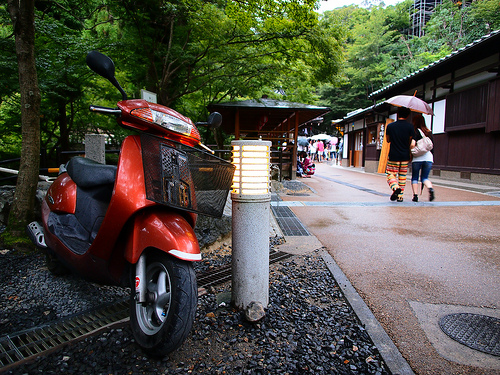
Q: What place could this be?
A: It is a walkway.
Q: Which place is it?
A: It is a walkway.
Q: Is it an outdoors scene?
A: Yes, it is outdoors.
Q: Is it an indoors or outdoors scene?
A: It is outdoors.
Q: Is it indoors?
A: No, it is outdoors.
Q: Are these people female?
A: No, they are both male and female.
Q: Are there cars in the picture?
A: No, there are no cars.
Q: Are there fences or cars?
A: No, there are no cars or fences.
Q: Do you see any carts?
A: No, there are no carts.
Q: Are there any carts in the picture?
A: No, there are no carts.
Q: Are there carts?
A: No, there are no carts.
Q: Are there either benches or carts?
A: No, there are no carts or benches.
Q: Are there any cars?
A: No, there are no cars.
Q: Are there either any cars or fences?
A: No, there are no cars or fences.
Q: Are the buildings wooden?
A: Yes, the buildings are wooden.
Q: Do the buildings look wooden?
A: Yes, the buildings are wooden.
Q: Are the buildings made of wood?
A: Yes, the buildings are made of wood.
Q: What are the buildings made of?
A: The buildings are made of wood.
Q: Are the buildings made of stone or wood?
A: The buildings are made of wood.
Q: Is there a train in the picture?
A: No, there are no trains.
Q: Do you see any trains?
A: No, there are no trains.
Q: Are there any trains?
A: No, there are no trains.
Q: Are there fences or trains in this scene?
A: No, there are no trains or fences.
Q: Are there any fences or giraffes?
A: No, there are no fences or giraffes.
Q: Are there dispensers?
A: No, there are no dispensers.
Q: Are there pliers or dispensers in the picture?
A: No, there are no dispensers or pliers.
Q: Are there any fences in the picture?
A: No, there are no fences.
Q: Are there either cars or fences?
A: No, there are no fences or cars.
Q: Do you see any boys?
A: No, there are no boys.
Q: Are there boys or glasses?
A: No, there are no boys or glasses.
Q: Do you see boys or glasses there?
A: No, there are no boys or glasses.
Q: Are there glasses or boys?
A: No, there are no boys or glasses.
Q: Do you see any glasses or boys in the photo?
A: No, there are no boys or glasses.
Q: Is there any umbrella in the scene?
A: Yes, there is an umbrella.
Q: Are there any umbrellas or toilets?
A: Yes, there is an umbrella.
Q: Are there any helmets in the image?
A: No, there are no helmets.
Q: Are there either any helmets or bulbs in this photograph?
A: No, there are no helmets or bulbs.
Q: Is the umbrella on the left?
A: No, the umbrella is on the right of the image.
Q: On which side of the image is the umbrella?
A: The umbrella is on the right of the image.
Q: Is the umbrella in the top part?
A: Yes, the umbrella is in the top of the image.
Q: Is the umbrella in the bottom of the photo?
A: No, the umbrella is in the top of the image.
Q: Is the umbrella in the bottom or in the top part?
A: The umbrella is in the top of the image.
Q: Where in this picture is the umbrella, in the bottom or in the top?
A: The umbrella is in the top of the image.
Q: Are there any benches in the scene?
A: No, there are no benches.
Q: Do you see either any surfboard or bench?
A: No, there are no benches or surfboards.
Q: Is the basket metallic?
A: Yes, the basket is metallic.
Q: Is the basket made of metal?
A: Yes, the basket is made of metal.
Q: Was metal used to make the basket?
A: Yes, the basket is made of metal.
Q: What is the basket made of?
A: The basket is made of metal.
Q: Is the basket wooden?
A: No, the basket is metallic.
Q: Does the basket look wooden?
A: No, the basket is metallic.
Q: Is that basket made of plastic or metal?
A: The basket is made of metal.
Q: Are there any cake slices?
A: No, there are no cake slices.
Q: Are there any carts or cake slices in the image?
A: No, there are no cake slices or carts.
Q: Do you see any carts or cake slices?
A: No, there are no cake slices or carts.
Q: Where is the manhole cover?
A: The manhole cover is on the street.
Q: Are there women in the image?
A: Yes, there is a woman.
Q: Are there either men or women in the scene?
A: Yes, there is a woman.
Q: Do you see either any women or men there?
A: Yes, there is a woman.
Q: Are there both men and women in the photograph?
A: Yes, there are both a woman and a man.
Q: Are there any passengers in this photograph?
A: No, there are no passengers.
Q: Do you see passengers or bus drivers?
A: No, there are no passengers or bus drivers.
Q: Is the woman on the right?
A: Yes, the woman is on the right of the image.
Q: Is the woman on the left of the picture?
A: No, the woman is on the right of the image.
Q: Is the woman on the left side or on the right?
A: The woman is on the right of the image.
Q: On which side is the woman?
A: The woman is on the right of the image.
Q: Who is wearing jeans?
A: The woman is wearing jeans.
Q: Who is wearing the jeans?
A: The woman is wearing jeans.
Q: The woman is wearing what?
A: The woman is wearing jeans.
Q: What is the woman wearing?
A: The woman is wearing jeans.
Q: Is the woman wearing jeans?
A: Yes, the woman is wearing jeans.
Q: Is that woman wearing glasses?
A: No, the woman is wearing jeans.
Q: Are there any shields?
A: No, there are no shields.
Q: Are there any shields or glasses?
A: No, there are no shields or glasses.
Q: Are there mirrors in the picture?
A: Yes, there is a mirror.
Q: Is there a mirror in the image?
A: Yes, there is a mirror.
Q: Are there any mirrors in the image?
A: Yes, there is a mirror.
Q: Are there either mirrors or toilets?
A: Yes, there is a mirror.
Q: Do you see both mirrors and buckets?
A: No, there is a mirror but no buckets.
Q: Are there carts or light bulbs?
A: No, there are no carts or light bulbs.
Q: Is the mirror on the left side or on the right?
A: The mirror is on the left of the image.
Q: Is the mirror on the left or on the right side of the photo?
A: The mirror is on the left of the image.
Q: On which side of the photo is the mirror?
A: The mirror is on the left of the image.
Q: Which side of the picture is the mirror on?
A: The mirror is on the left of the image.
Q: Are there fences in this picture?
A: No, there are no fences.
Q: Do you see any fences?
A: No, there are no fences.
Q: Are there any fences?
A: No, there are no fences.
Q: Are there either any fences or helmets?
A: No, there are no fences or helmets.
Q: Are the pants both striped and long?
A: Yes, the pants are striped and long.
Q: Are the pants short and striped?
A: No, the pants are striped but long.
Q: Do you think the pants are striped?
A: Yes, the pants are striped.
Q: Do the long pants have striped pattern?
A: Yes, the pants are striped.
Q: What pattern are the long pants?
A: The trousers are striped.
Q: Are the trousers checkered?
A: No, the trousers are striped.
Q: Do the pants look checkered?
A: No, the pants are striped.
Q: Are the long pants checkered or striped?
A: The pants are striped.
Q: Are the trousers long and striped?
A: Yes, the trousers are long and striped.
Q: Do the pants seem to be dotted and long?
A: No, the pants are long but striped.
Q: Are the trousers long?
A: Yes, the trousers are long.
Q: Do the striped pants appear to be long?
A: Yes, the trousers are long.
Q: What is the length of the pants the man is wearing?
A: The pants are long.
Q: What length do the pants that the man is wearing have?
A: The pants have long length.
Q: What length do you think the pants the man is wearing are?
A: The pants are long.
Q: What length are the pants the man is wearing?
A: The pants are long.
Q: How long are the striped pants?
A: The pants are long.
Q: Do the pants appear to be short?
A: No, the pants are long.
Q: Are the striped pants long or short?
A: The trousers are long.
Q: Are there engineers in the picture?
A: No, there are no engineers.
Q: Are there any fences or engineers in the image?
A: No, there are no engineers or fences.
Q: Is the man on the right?
A: Yes, the man is on the right of the image.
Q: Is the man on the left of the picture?
A: No, the man is on the right of the image.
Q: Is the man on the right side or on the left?
A: The man is on the right of the image.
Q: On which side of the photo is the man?
A: The man is on the right of the image.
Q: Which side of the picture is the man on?
A: The man is on the right of the image.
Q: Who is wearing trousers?
A: The man is wearing trousers.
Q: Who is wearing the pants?
A: The man is wearing trousers.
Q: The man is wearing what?
A: The man is wearing pants.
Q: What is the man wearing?
A: The man is wearing pants.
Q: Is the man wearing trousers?
A: Yes, the man is wearing trousers.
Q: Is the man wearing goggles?
A: No, the man is wearing trousers.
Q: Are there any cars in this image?
A: No, there are no cars.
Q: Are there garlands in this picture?
A: No, there are no garlands.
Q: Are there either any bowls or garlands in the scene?
A: No, there are no garlands or bowls.